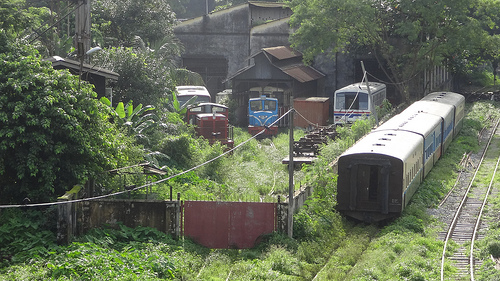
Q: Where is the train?
A: Track.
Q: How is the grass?
A: High.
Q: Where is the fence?
A: Around junk.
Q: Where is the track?
A: Junk yard.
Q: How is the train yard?
A: Ran down.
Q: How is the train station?
A: Abondoned.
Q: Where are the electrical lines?
A: Above the yard.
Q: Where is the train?
A: Track.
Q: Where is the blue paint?
A: Train.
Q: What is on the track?
A: Old train cars.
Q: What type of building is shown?
A: A storage building.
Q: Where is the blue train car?
A: In the storage building.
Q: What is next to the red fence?
A: A pole.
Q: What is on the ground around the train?
A: Green grass.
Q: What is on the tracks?
A: Train cars.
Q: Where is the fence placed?
A: Around yard.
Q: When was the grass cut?
A: Long ago.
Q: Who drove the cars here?
A: Conductor.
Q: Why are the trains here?
A: Storage.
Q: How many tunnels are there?
A: Two.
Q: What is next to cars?
A: Tracks.